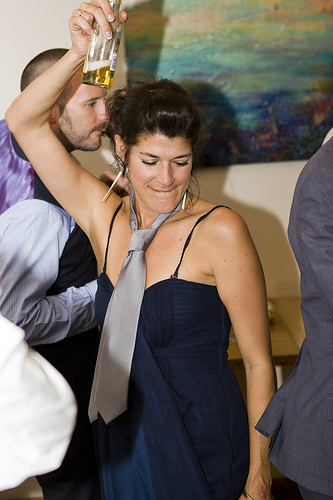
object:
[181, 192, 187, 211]
ear ring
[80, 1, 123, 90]
bottle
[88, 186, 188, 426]
tie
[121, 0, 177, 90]
shadow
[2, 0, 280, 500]
woman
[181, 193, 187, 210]
earring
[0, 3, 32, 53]
wall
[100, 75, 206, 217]
brown hair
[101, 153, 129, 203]
white earring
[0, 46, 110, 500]
man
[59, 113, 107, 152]
beard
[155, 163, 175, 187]
nose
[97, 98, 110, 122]
nose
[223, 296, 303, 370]
desk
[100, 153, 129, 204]
earring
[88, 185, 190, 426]
gray tie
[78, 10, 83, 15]
ring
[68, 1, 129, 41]
finger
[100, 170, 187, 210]
gold earrings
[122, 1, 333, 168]
painting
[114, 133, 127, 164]
ear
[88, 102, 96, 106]
eye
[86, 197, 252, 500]
dress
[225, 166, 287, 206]
background